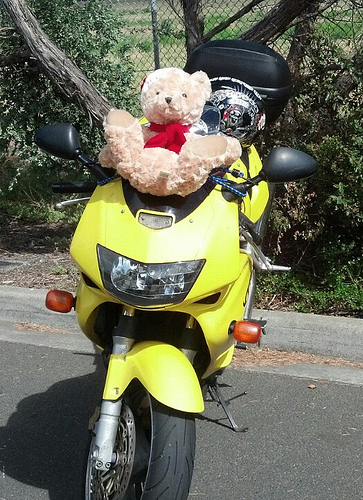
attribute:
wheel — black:
[76, 383, 195, 498]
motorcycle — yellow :
[40, 50, 318, 498]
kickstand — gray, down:
[211, 377, 249, 432]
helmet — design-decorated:
[179, 75, 269, 150]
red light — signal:
[232, 321, 263, 343]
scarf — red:
[144, 122, 188, 151]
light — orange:
[231, 316, 264, 346]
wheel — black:
[82, 390, 196, 498]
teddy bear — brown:
[103, 65, 244, 213]